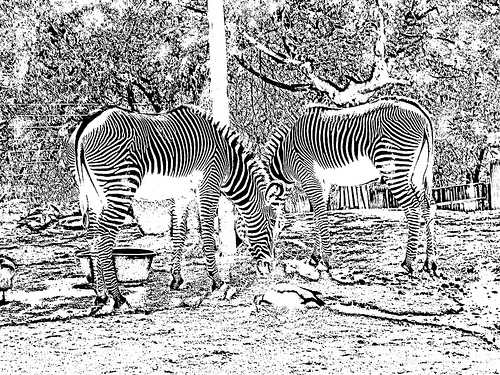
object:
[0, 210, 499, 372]
grass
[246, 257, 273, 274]
mouth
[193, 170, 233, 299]
feet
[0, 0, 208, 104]
trees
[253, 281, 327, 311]
stone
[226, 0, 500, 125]
trees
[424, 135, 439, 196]
tail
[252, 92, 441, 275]
zebra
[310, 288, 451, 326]
ground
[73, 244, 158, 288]
basin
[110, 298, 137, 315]
hooves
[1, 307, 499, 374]
no objects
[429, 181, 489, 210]
fence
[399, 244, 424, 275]
zebra hooves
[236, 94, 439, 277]
zebra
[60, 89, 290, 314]
zebra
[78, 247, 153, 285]
bowl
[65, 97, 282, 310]
zebra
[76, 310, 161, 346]
floor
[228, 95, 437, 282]
zebra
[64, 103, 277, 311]
zebra